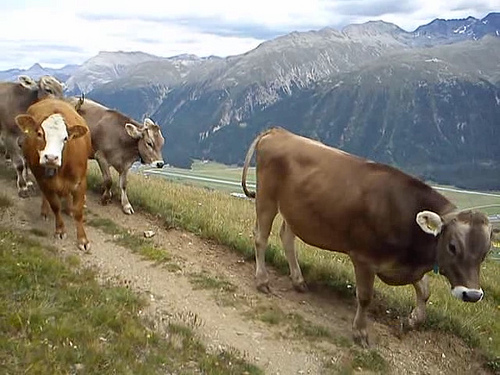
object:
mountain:
[2, 2, 497, 192]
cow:
[242, 127, 478, 331]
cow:
[13, 95, 95, 257]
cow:
[66, 95, 168, 215]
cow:
[0, 73, 67, 200]